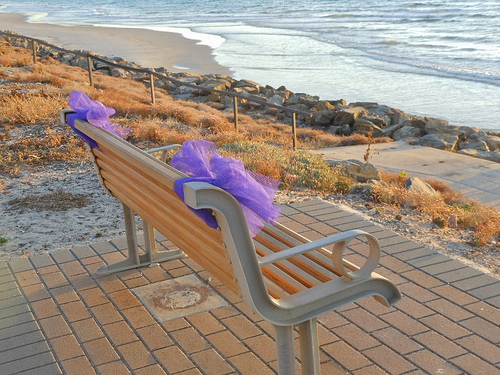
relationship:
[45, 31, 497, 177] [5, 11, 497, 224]
rocks along shore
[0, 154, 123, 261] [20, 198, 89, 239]
area of sand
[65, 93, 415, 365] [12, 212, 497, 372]
bench on bricks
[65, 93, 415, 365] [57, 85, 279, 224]
bench with bows